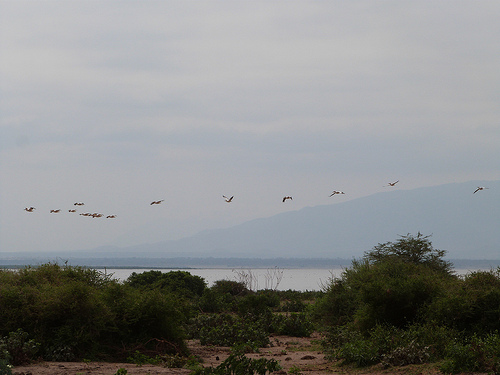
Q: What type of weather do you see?
A: It is cloudy.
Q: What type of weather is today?
A: It is cloudy.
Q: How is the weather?
A: It is cloudy.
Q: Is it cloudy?
A: Yes, it is cloudy.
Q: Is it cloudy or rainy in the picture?
A: It is cloudy.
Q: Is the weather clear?
A: No, it is cloudy.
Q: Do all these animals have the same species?
A: Yes, all the animals are birds.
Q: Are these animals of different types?
A: No, all the animals are birds.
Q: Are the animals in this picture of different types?
A: No, all the animals are birds.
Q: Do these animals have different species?
A: No, all the animals are birds.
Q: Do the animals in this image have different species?
A: No, all the animals are birds.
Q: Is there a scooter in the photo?
A: No, there are no scooters.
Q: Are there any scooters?
A: No, there are no scooters.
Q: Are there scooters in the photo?
A: No, there are no scooters.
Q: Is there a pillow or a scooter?
A: No, there are no scooters or pillows.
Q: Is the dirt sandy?
A: Yes, the dirt is sandy.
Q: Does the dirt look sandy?
A: Yes, the dirt is sandy.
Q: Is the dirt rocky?
A: No, the dirt is sandy.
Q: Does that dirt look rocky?
A: No, the dirt is sandy.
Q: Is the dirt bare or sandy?
A: The dirt is sandy.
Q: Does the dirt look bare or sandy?
A: The dirt is sandy.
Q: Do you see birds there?
A: Yes, there are birds.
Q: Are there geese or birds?
A: Yes, there are birds.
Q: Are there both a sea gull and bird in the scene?
A: No, there are birds but no seagulls.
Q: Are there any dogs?
A: No, there are no dogs.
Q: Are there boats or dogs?
A: No, there are no dogs or boats.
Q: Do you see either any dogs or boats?
A: No, there are no dogs or boats.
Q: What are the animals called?
A: The animals are birds.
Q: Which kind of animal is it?
A: The animals are birds.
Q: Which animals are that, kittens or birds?
A: These are birds.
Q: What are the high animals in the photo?
A: The animals are birds.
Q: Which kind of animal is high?
A: The animal is birds.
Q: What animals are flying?
A: The animals are birds.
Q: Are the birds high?
A: Yes, the birds are high.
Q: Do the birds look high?
A: Yes, the birds are high.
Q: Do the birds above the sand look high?
A: Yes, the birds are high.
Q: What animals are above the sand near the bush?
A: The animals are birds.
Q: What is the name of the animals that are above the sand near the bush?
A: The animals are birds.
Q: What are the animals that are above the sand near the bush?
A: The animals are birds.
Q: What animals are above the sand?
A: The animals are birds.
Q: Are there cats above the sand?
A: No, there are birds above the sand.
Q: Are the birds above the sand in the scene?
A: Yes, the birds are above the sand.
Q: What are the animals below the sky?
A: The animals are birds.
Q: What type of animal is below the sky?
A: The animals are birds.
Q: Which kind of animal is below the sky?
A: The animals are birds.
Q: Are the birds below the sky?
A: Yes, the birds are below the sky.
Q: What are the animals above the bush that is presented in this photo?
A: The animals are birds.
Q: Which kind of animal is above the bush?
A: The animals are birds.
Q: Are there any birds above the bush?
A: Yes, there are birds above the bush.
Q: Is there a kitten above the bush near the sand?
A: No, there are birds above the shrub.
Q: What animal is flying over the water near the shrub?
A: The birds are flying over the water.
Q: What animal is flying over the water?
A: The birds are flying over the water.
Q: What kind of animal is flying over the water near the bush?
A: The animals are birds.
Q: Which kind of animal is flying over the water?
A: The animals are birds.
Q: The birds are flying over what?
A: The birds are flying over the water.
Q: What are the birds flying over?
A: The birds are flying over the water.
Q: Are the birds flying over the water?
A: Yes, the birds are flying over the water.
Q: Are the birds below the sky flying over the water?
A: Yes, the birds are flying over the water.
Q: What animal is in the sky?
A: The birds are in the sky.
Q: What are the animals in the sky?
A: The animals are birds.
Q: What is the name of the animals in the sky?
A: The animals are birds.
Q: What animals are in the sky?
A: The animals are birds.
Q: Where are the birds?
A: The birds are in the sky.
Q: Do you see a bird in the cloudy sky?
A: Yes, there are birds in the sky.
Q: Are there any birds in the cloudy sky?
A: Yes, there are birds in the sky.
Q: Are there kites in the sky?
A: No, there are birds in the sky.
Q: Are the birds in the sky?
A: Yes, the birds are in the sky.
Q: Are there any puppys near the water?
A: No, there are birds near the water.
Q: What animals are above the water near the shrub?
A: The animals are birds.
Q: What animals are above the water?
A: The animals are birds.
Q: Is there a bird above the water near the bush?
A: Yes, there are birds above the water.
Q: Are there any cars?
A: No, there are no cars.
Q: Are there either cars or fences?
A: No, there are no cars or fences.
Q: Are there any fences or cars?
A: No, there are no cars or fences.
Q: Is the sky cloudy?
A: Yes, the sky is cloudy.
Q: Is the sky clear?
A: No, the sky is cloudy.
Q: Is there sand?
A: Yes, there is sand.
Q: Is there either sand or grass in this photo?
A: Yes, there is sand.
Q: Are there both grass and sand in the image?
A: No, there is sand but no grass.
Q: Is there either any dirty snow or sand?
A: Yes, there is dirty sand.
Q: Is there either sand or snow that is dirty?
A: Yes, the sand is dirty.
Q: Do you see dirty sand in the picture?
A: Yes, there is dirty sand.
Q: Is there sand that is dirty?
A: Yes, there is sand that is dirty.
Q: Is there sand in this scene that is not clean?
A: Yes, there is dirty sand.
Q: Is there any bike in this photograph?
A: No, there are no bikes.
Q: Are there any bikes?
A: No, there are no bikes.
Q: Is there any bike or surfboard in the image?
A: No, there are no bikes or surfboards.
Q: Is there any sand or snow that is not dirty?
A: No, there is sand but it is dirty.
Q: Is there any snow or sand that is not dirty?
A: No, there is sand but it is dirty.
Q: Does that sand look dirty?
A: Yes, the sand is dirty.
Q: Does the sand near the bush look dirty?
A: Yes, the sand is dirty.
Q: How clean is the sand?
A: The sand is dirty.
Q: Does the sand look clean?
A: No, the sand is dirty.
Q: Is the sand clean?
A: No, the sand is dirty.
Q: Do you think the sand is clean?
A: No, the sand is dirty.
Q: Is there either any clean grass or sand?
A: No, there is sand but it is dirty.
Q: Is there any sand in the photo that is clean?
A: No, there is sand but it is dirty.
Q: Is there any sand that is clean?
A: No, there is sand but it is dirty.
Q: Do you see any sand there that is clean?
A: No, there is sand but it is dirty.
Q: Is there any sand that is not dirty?
A: No, there is sand but it is dirty.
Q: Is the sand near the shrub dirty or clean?
A: The sand is dirty.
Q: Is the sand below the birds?
A: Yes, the sand is below the birds.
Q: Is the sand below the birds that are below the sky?
A: Yes, the sand is below the birds.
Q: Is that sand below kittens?
A: No, the sand is below the birds.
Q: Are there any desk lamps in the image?
A: No, there are no desk lamps.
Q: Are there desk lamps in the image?
A: No, there are no desk lamps.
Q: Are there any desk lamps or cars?
A: No, there are no desk lamps or cars.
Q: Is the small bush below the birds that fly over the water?
A: Yes, the bush is below the birds.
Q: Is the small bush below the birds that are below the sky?
A: Yes, the bush is below the birds.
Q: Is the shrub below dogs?
A: No, the shrub is below the birds.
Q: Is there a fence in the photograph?
A: No, there are no fences.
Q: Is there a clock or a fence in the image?
A: No, there are no fences or clocks.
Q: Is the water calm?
A: Yes, the water is calm.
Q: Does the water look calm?
A: Yes, the water is calm.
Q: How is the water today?
A: The water is calm.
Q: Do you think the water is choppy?
A: No, the water is calm.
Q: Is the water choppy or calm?
A: The water is calm.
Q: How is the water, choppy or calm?
A: The water is calm.